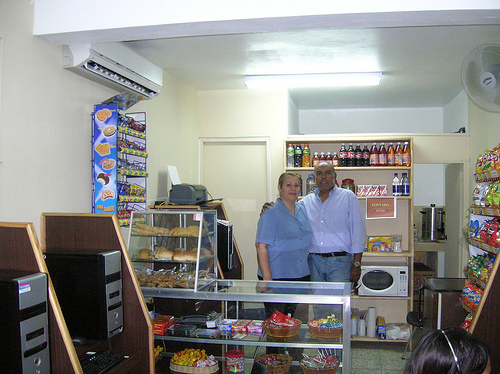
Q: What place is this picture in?
A: It is at the cafe.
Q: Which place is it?
A: It is a cafe.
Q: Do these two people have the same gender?
A: No, they are both male and female.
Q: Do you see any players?
A: No, there are no players.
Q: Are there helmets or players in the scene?
A: No, there are no players or helmets.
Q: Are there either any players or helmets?
A: No, there are no players or helmets.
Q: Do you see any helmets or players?
A: No, there are no players or helmets.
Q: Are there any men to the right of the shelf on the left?
A: Yes, there is a man to the right of the shelf.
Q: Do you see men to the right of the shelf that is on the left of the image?
A: Yes, there is a man to the right of the shelf.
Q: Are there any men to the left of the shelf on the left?
A: No, the man is to the right of the shelf.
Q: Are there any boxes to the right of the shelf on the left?
A: No, there is a man to the right of the shelf.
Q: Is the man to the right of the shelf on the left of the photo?
A: Yes, the man is to the right of the shelf.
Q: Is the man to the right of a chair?
A: No, the man is to the right of the shelf.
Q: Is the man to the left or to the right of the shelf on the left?
A: The man is to the right of the shelf.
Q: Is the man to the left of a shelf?
A: Yes, the man is to the left of a shelf.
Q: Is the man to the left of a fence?
A: No, the man is to the left of a shelf.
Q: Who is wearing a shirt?
A: The man is wearing a shirt.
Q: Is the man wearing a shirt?
A: Yes, the man is wearing a shirt.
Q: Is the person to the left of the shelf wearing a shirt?
A: Yes, the man is wearing a shirt.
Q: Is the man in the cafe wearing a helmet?
A: No, the man is wearing a shirt.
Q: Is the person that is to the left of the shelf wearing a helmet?
A: No, the man is wearing a shirt.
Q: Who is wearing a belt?
A: The man is wearing a belt.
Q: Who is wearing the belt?
A: The man is wearing a belt.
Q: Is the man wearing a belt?
A: Yes, the man is wearing a belt.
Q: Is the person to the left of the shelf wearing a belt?
A: Yes, the man is wearing a belt.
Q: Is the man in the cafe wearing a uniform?
A: No, the man is wearing a belt.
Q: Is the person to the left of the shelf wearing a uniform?
A: No, the man is wearing a belt.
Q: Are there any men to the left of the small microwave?
A: Yes, there is a man to the left of the microwave.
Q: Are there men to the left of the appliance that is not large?
A: Yes, there is a man to the left of the microwave.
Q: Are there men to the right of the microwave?
A: No, the man is to the left of the microwave.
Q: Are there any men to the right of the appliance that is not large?
A: No, the man is to the left of the microwave.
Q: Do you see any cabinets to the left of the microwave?
A: No, there is a man to the left of the microwave.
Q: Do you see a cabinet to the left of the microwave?
A: No, there is a man to the left of the microwave.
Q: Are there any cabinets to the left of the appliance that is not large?
A: No, there is a man to the left of the microwave.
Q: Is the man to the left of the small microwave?
A: Yes, the man is to the left of the microwave.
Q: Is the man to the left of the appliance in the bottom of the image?
A: Yes, the man is to the left of the microwave.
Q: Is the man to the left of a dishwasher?
A: No, the man is to the left of the microwave.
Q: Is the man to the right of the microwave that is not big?
A: No, the man is to the left of the microwave.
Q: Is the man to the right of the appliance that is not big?
A: No, the man is to the left of the microwave.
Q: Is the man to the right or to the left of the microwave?
A: The man is to the left of the microwave.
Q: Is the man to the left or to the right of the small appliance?
A: The man is to the left of the microwave.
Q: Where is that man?
A: The man is in the cafe.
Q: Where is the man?
A: The man is in the cafe.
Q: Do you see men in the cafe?
A: Yes, there is a man in the cafe.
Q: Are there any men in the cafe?
A: Yes, there is a man in the cafe.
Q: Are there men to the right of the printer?
A: Yes, there is a man to the right of the printer.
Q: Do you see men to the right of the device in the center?
A: Yes, there is a man to the right of the printer.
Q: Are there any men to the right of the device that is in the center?
A: Yes, there is a man to the right of the printer.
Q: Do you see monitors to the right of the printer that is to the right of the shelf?
A: No, there is a man to the right of the printer.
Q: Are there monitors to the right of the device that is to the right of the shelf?
A: No, there is a man to the right of the printer.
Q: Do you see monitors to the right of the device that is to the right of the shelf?
A: No, there is a man to the right of the printer.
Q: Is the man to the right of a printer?
A: Yes, the man is to the right of a printer.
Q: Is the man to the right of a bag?
A: No, the man is to the right of a printer.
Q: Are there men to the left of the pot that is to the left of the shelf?
A: Yes, there is a man to the left of the pot.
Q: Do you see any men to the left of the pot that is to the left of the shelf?
A: Yes, there is a man to the left of the pot.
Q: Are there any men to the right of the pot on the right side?
A: No, the man is to the left of the pot.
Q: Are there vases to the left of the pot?
A: No, there is a man to the left of the pot.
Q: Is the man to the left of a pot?
A: Yes, the man is to the left of a pot.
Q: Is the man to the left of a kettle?
A: No, the man is to the left of a pot.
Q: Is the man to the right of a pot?
A: No, the man is to the left of a pot.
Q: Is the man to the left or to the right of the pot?
A: The man is to the left of the pot.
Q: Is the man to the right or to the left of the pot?
A: The man is to the left of the pot.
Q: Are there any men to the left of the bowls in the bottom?
A: Yes, there is a man to the left of the bowls.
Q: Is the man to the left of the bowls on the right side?
A: Yes, the man is to the left of the bowls.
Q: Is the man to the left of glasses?
A: No, the man is to the left of the bowls.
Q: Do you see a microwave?
A: Yes, there is a microwave.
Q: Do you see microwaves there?
A: Yes, there is a microwave.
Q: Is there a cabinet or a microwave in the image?
A: Yes, there is a microwave.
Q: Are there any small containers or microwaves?
A: Yes, there is a small microwave.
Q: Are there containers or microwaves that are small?
A: Yes, the microwave is small.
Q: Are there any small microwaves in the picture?
A: Yes, there is a small microwave.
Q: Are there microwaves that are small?
A: Yes, there is a small microwave.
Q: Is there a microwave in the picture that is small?
A: Yes, there is a microwave that is small.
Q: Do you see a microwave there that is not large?
A: Yes, there is a small microwave.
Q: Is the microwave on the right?
A: Yes, the microwave is on the right of the image.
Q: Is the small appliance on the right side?
A: Yes, the microwave is on the right of the image.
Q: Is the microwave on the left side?
A: No, the microwave is on the right of the image.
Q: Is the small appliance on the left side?
A: No, the microwave is on the right of the image.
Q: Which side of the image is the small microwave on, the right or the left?
A: The microwave is on the right of the image.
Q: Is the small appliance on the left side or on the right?
A: The microwave is on the right of the image.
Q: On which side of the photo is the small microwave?
A: The microwave is on the right of the image.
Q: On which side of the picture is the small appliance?
A: The microwave is on the right of the image.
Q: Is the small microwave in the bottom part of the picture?
A: Yes, the microwave is in the bottom of the image.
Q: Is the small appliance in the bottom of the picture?
A: Yes, the microwave is in the bottom of the image.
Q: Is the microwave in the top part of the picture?
A: No, the microwave is in the bottom of the image.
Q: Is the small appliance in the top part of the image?
A: No, the microwave is in the bottom of the image.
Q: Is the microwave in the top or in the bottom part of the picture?
A: The microwave is in the bottom of the image.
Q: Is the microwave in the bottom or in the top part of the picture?
A: The microwave is in the bottom of the image.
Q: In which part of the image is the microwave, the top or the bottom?
A: The microwave is in the bottom of the image.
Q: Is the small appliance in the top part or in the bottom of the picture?
A: The microwave is in the bottom of the image.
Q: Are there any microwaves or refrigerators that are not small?
A: No, there is a microwave but it is small.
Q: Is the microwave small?
A: Yes, the microwave is small.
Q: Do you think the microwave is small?
A: Yes, the microwave is small.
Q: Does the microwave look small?
A: Yes, the microwave is small.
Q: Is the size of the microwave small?
A: Yes, the microwave is small.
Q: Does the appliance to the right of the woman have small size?
A: Yes, the microwave is small.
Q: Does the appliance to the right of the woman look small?
A: Yes, the microwave is small.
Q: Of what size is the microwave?
A: The microwave is small.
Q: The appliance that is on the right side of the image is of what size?
A: The microwave is small.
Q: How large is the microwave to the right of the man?
A: The microwave is small.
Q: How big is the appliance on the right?
A: The microwave is small.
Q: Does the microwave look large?
A: No, the microwave is small.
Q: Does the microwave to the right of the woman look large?
A: No, the microwave is small.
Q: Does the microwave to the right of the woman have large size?
A: No, the microwave is small.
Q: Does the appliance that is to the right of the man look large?
A: No, the microwave is small.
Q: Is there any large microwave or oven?
A: No, there is a microwave but it is small.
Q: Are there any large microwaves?
A: No, there is a microwave but it is small.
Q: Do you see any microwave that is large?
A: No, there is a microwave but it is small.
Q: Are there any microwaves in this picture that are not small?
A: No, there is a microwave but it is small.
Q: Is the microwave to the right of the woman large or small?
A: The microwave is small.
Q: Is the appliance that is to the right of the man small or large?
A: The microwave is small.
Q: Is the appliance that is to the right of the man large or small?
A: The microwave is small.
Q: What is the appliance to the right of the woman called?
A: The appliance is a microwave.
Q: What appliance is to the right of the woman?
A: The appliance is a microwave.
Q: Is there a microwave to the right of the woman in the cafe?
A: Yes, there is a microwave to the right of the woman.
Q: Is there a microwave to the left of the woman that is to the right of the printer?
A: No, the microwave is to the right of the woman.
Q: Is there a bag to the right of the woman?
A: No, there is a microwave to the right of the woman.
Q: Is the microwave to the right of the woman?
A: Yes, the microwave is to the right of the woman.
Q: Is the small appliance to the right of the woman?
A: Yes, the microwave is to the right of the woman.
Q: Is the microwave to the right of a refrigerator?
A: No, the microwave is to the right of the woman.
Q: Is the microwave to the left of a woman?
A: No, the microwave is to the right of a woman.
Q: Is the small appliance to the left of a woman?
A: No, the microwave is to the right of a woman.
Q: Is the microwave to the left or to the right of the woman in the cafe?
A: The microwave is to the right of the woman.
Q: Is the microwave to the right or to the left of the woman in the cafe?
A: The microwave is to the right of the woman.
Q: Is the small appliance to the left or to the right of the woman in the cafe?
A: The microwave is to the right of the woman.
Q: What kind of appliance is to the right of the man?
A: The appliance is a microwave.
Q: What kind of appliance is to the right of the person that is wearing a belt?
A: The appliance is a microwave.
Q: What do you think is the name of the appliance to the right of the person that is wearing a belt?
A: The appliance is a microwave.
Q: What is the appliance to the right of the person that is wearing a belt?
A: The appliance is a microwave.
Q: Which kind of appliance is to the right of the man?
A: The appliance is a microwave.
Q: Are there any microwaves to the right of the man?
A: Yes, there is a microwave to the right of the man.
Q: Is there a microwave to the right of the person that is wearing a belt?
A: Yes, there is a microwave to the right of the man.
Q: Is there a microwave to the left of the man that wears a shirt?
A: No, the microwave is to the right of the man.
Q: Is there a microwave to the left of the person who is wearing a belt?
A: No, the microwave is to the right of the man.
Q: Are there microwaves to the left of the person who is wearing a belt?
A: No, the microwave is to the right of the man.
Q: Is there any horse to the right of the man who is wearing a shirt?
A: No, there is a microwave to the right of the man.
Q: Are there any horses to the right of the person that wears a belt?
A: No, there is a microwave to the right of the man.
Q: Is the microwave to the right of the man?
A: Yes, the microwave is to the right of the man.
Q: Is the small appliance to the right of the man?
A: Yes, the microwave is to the right of the man.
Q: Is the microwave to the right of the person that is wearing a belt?
A: Yes, the microwave is to the right of the man.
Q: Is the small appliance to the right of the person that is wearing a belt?
A: Yes, the microwave is to the right of the man.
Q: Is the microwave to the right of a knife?
A: No, the microwave is to the right of the man.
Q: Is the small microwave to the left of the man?
A: No, the microwave is to the right of the man.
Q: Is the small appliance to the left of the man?
A: No, the microwave is to the right of the man.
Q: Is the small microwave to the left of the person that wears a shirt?
A: No, the microwave is to the right of the man.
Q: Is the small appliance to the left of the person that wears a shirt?
A: No, the microwave is to the right of the man.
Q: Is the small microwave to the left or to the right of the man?
A: The microwave is to the right of the man.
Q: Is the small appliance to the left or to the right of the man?
A: The microwave is to the right of the man.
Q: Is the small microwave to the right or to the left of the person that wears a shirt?
A: The microwave is to the right of the man.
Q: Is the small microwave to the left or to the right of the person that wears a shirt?
A: The microwave is to the right of the man.